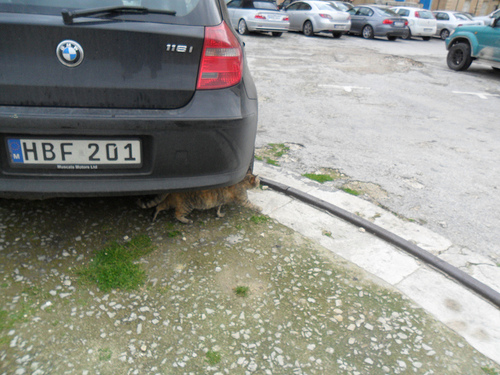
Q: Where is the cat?
A: Under the black car.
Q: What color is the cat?
A: Gold with brown stripes.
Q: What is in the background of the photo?
A: Cars.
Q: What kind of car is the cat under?
A: A BMW.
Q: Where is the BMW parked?
A: On a patchy grass and gravel parking area.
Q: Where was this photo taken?
A: In a parking lot.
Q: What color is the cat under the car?
A: Orange and grey.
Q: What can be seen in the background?
A: A line of cars parked.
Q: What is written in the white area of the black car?
A: HBF 201.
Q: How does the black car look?
A: Dusty.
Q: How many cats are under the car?
A: One.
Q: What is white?
A: License plate.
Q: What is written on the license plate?
A: HBF 201.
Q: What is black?
A: Car.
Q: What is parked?
A: Cars.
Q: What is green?
A: Patches of grass.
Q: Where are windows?
A: On cars.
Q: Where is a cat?
A: Under a car.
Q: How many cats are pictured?
A: One.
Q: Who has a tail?
A: The cat.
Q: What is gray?
A: The pavement.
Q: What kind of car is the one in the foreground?
A: BMW.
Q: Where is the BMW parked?
A: On the curb.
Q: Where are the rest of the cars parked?
A: In the parking lot.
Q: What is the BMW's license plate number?
A: HBF 201.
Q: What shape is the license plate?
A: Rectangular.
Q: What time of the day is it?
A: Daytime.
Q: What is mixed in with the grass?
A: Stones.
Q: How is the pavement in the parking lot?
A: In need of repair.